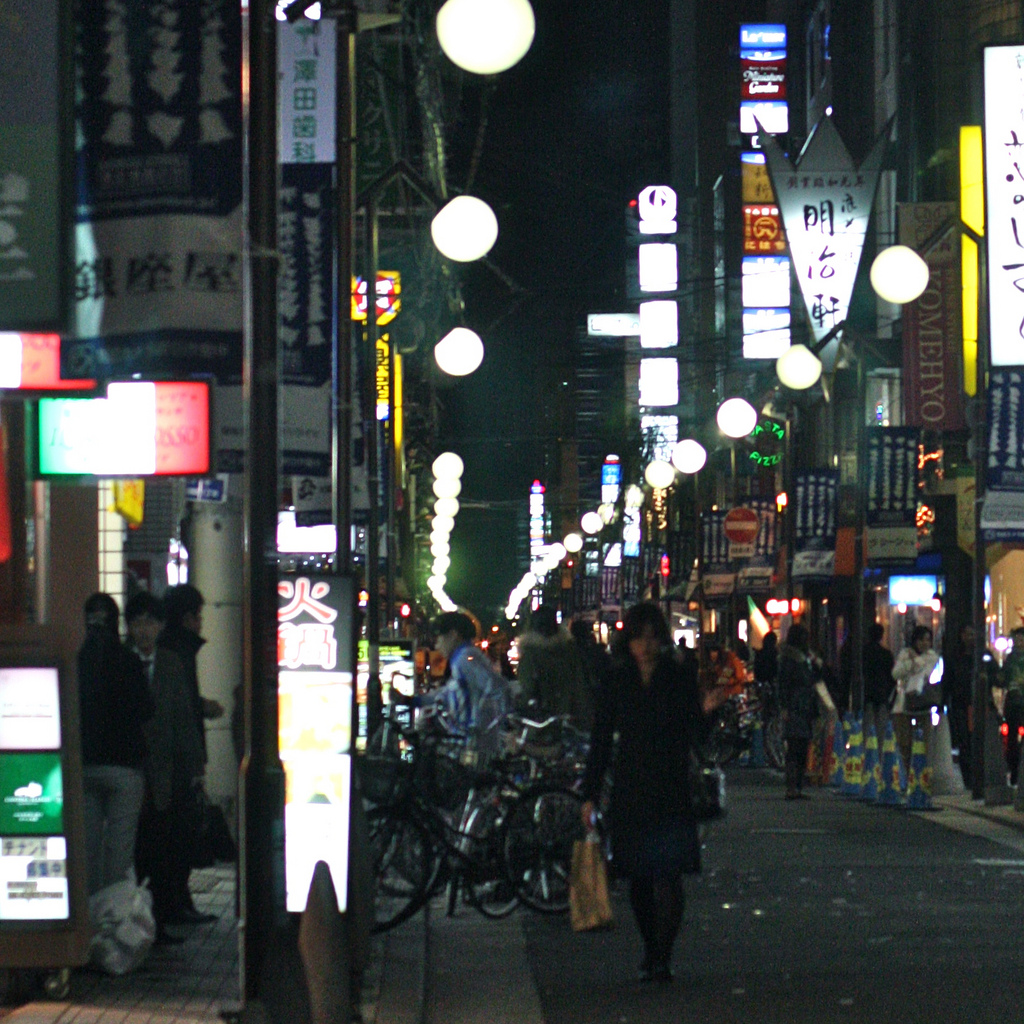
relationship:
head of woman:
[619, 604, 672, 665] [580, 602, 728, 1011]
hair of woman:
[617, 604, 672, 665] [589, 602, 717, 1002]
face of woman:
[630, 626, 667, 663] [601, 600, 720, 1017]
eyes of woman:
[625, 626, 665, 646] [580, 602, 728, 1011]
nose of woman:
[640, 628, 653, 646] [580, 602, 728, 1011]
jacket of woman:
[576, 637, 715, 836] [580, 602, 728, 1011]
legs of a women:
[618, 876, 698, 965] [602, 597, 702, 986]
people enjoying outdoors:
[62, 538, 989, 742] [92, 189, 961, 645]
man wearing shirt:
[409, 595, 557, 799] [428, 656, 532, 801]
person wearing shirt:
[888, 608, 966, 749] [890, 648, 955, 707]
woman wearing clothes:
[555, 562, 793, 1016] [584, 569, 792, 997]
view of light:
[97, 40, 964, 952] [430, 195, 499, 263]